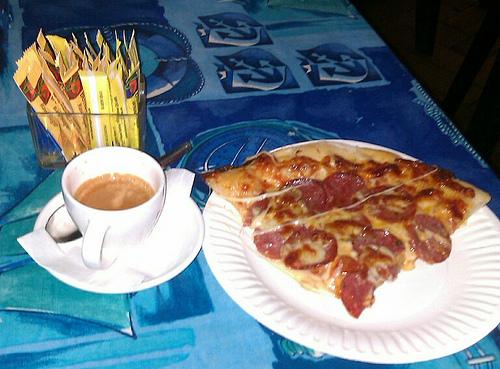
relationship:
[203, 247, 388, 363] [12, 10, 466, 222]
paper plate on table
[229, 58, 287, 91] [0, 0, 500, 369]
anchor on table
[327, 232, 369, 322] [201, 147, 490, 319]
pepperoni hanging off of pepperoni pizza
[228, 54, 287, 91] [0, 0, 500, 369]
anchor on table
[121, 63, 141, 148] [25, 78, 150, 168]
packets are in a container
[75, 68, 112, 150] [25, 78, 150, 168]
packets are in a container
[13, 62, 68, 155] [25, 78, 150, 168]
packets are in a container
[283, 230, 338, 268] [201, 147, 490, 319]
pepperoni on pepperoni pizza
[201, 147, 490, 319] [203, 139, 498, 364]
pepperoni pizza on a plate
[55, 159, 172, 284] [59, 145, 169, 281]
napkin under cup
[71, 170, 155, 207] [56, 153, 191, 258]
tea inside of a cup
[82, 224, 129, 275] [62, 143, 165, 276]
handle on a cup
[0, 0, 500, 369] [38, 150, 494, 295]
table has plates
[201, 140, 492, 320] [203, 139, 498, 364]
pepperoni pizza on a plate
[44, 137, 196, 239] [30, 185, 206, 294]
spoon on a saucer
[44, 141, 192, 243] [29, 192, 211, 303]
spoon hanging off a saucer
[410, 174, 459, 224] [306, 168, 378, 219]
cheese on top of pepperoni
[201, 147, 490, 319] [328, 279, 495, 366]
pepperoni pizza on plate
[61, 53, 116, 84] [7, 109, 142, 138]
objects on dish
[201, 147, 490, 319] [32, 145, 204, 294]
pepperoni pizza near coffee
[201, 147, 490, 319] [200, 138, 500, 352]
pepperoni pizza on dish